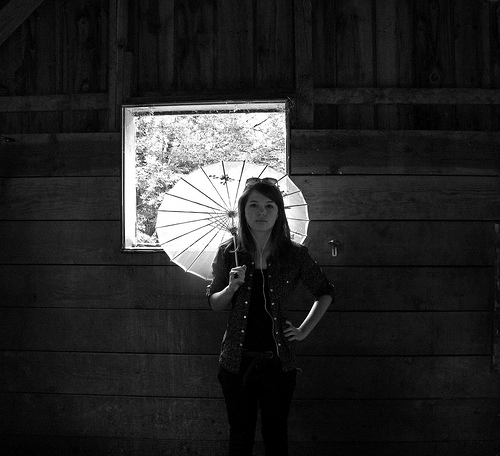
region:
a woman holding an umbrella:
[149, 144, 344, 452]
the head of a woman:
[236, 173, 286, 233]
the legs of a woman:
[218, 378, 305, 453]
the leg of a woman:
[258, 388, 296, 453]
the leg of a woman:
[217, 370, 257, 454]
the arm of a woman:
[283, 241, 335, 346]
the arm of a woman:
[203, 236, 247, 314]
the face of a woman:
[250, 198, 275, 225]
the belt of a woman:
[236, 346, 279, 363]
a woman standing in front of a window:
[124, 100, 320, 292]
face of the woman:
[227, 190, 281, 237]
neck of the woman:
[255, 231, 273, 251]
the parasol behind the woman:
[165, 202, 205, 273]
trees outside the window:
[168, 105, 280, 150]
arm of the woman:
[266, 295, 321, 346]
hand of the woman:
[221, 262, 241, 285]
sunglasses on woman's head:
[241, 175, 277, 195]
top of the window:
[120, 97, 290, 113]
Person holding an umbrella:
[150, 159, 336, 451]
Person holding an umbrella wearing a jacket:
[155, 158, 335, 455]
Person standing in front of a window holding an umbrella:
[116, 94, 336, 454]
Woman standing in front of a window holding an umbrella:
[112, 90, 335, 453]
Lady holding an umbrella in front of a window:
[112, 88, 338, 454]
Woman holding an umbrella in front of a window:
[112, 92, 334, 454]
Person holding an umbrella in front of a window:
[115, 90, 337, 455]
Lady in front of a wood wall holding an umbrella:
[147, 155, 342, 454]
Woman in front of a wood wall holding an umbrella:
[152, 160, 337, 453]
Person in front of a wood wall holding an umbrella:
[152, 158, 338, 454]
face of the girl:
[217, 178, 284, 229]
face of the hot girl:
[218, 166, 319, 248]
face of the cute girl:
[201, 153, 290, 263]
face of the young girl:
[220, 171, 294, 251]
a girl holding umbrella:
[126, 130, 351, 307]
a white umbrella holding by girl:
[119, 126, 344, 293]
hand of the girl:
[216, 246, 248, 298]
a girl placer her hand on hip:
[280, 278, 337, 368]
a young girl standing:
[136, 135, 371, 450]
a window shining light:
[122, 103, 287, 250]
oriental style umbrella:
[154, 158, 310, 284]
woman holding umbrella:
[153, 158, 337, 453]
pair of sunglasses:
[245, 175, 281, 190]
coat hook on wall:
[328, 237, 339, 258]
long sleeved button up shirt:
[204, 235, 339, 377]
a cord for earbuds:
[242, 207, 281, 321]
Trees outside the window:
[131, 110, 283, 245]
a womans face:
[240, 175, 281, 231]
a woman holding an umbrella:
[145, 156, 330, 306]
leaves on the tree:
[149, 146, 179, 166]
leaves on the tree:
[247, 138, 281, 163]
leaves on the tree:
[213, 141, 250, 158]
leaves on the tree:
[147, 219, 163, 250]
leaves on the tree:
[141, 171, 177, 202]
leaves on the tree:
[168, 151, 197, 167]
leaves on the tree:
[164, 118, 201, 158]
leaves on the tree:
[198, 133, 248, 160]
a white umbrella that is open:
[150, 131, 335, 292]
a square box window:
[99, 98, 324, 261]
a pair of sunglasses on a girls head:
[243, 173, 288, 196]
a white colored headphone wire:
[249, 240, 298, 367]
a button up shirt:
[205, 230, 331, 377]